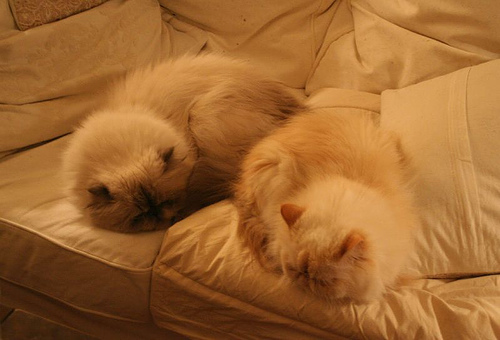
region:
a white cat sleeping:
[58, 53, 313, 231]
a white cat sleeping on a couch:
[236, 107, 420, 304]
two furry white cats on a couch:
[63, 55, 418, 302]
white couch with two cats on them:
[0, 1, 499, 339]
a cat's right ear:
[280, 203, 305, 228]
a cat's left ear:
[337, 226, 371, 258]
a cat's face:
[281, 233, 348, 298]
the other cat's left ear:
[146, 143, 180, 170]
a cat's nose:
[150, 205, 169, 220]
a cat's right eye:
[127, 209, 149, 226]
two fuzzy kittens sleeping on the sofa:
[58, 50, 423, 305]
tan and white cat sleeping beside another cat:
[235, 109, 415, 305]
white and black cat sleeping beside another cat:
[67, 52, 298, 234]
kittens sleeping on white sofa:
[60, 52, 417, 306]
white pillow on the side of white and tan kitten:
[378, 59, 495, 278]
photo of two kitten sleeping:
[2, 3, 498, 338]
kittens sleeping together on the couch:
[2, 2, 498, 338]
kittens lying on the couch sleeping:
[2, 3, 498, 335]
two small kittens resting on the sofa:
[1, 0, 496, 337]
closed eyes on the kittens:
[124, 191, 337, 303]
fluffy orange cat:
[246, 129, 414, 309]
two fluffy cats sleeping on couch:
[67, 62, 435, 314]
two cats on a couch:
[81, 66, 413, 311]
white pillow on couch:
[400, 60, 497, 203]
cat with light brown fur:
[69, 54, 258, 221]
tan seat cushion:
[5, 180, 163, 337]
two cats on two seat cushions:
[88, 81, 403, 307]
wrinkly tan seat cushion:
[177, 229, 326, 336]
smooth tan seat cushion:
[1, 174, 111, 276]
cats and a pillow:
[85, 55, 496, 307]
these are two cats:
[83, 100, 384, 267]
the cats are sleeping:
[99, 75, 356, 216]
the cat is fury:
[292, 143, 392, 228]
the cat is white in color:
[307, 136, 384, 204]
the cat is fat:
[63, 105, 235, 214]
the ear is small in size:
[340, 230, 376, 258]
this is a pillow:
[435, 79, 483, 135]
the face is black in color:
[133, 195, 175, 224]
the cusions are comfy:
[100, 232, 230, 316]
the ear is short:
[275, 200, 302, 230]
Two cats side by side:
[67, 32, 427, 308]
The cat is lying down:
[61, 25, 263, 227]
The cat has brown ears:
[57, 35, 261, 227]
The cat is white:
[240, 81, 418, 302]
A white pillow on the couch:
[351, 36, 496, 276]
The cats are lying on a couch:
[37, 5, 412, 316]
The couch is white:
[21, 11, 460, 325]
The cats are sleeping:
[68, 9, 420, 319]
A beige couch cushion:
[17, 19, 203, 126]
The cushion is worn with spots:
[16, 22, 155, 105]